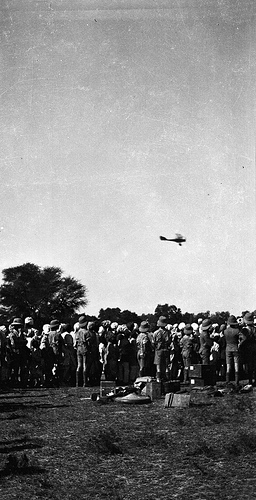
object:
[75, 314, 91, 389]
person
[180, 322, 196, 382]
person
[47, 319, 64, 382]
person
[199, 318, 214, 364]
person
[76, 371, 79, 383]
socks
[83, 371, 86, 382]
socks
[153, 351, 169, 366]
shorts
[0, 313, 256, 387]
suspenders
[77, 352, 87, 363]
shorts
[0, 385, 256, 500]
grass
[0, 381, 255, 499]
field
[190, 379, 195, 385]
white label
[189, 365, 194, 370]
white label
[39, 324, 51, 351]
woman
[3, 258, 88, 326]
tree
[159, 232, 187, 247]
airplane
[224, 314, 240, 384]
person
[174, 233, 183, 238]
wing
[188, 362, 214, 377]
box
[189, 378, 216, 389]
box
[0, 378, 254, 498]
ground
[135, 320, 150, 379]
person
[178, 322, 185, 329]
hat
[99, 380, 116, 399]
boxes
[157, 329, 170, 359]
bags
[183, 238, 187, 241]
nose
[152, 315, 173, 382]
person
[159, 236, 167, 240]
tail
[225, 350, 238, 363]
pants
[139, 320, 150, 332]
hat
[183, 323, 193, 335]
hat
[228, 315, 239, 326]
hat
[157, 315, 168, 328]
hat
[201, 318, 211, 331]
hat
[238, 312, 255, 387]
person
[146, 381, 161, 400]
boxes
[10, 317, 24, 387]
people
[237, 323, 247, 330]
camera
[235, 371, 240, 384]
boots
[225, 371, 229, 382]
socks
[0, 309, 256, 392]
crowd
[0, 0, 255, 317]
sky